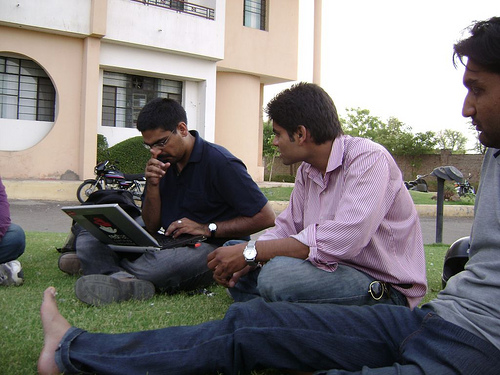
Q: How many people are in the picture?
A: 4.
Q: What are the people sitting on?
A: Grass.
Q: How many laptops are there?
A: 1.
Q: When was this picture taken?
A: During the day.